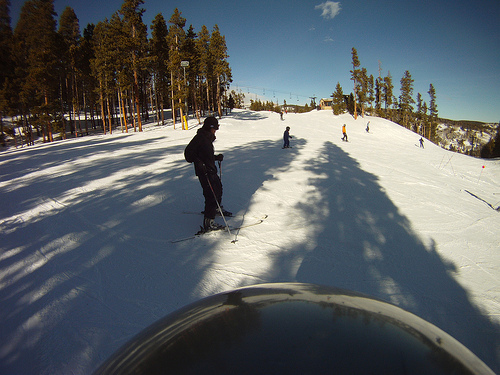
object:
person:
[280, 111, 286, 121]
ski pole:
[203, 166, 239, 247]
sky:
[0, 0, 499, 127]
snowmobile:
[90, 281, 496, 375]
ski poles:
[218, 159, 222, 181]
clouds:
[306, 0, 342, 43]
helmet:
[91, 280, 500, 375]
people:
[449, 142, 469, 154]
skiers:
[279, 107, 425, 150]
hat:
[203, 117, 220, 130]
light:
[180, 61, 189, 68]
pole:
[183, 67, 188, 115]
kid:
[282, 126, 293, 150]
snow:
[0, 93, 500, 375]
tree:
[119, 0, 146, 132]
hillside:
[0, 105, 500, 375]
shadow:
[0, 133, 500, 375]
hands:
[197, 161, 208, 177]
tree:
[91, 14, 114, 136]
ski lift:
[231, 83, 309, 103]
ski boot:
[194, 215, 226, 236]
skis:
[168, 219, 266, 245]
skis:
[181, 210, 268, 220]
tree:
[56, 0, 87, 140]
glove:
[215, 154, 224, 162]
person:
[340, 123, 348, 141]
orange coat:
[341, 126, 346, 134]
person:
[183, 115, 234, 235]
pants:
[198, 174, 224, 220]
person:
[419, 137, 425, 149]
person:
[365, 121, 371, 133]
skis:
[366, 132, 374, 135]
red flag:
[476, 165, 486, 185]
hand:
[215, 153, 224, 161]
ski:
[172, 213, 269, 245]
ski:
[179, 208, 256, 219]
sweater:
[342, 126, 347, 134]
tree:
[427, 83, 440, 145]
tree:
[397, 68, 417, 129]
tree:
[374, 59, 395, 119]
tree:
[349, 47, 374, 119]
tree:
[330, 81, 348, 116]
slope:
[0, 105, 500, 375]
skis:
[281, 146, 292, 149]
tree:
[0, 0, 56, 149]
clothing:
[184, 115, 235, 233]